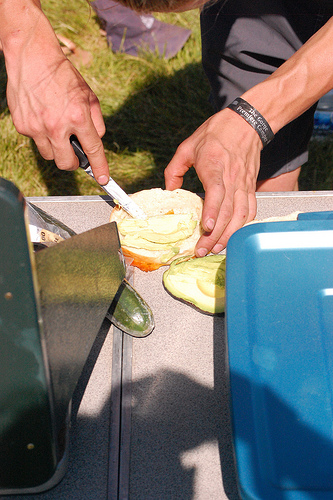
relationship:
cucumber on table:
[103, 280, 155, 338] [31, 189, 332, 498]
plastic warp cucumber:
[105, 280, 153, 337] [104, 277, 152, 337]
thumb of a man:
[163, 148, 188, 189] [0, 0, 333, 259]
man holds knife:
[6, 0, 329, 254] [67, 129, 136, 213]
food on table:
[110, 188, 206, 270] [31, 189, 332, 498]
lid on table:
[221, 216, 331, 408] [137, 277, 236, 446]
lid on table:
[0, 177, 94, 483] [23, 189, 297, 498]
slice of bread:
[117, 192, 201, 235] [117, 236, 196, 264]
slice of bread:
[118, 212, 194, 246] [121, 255, 170, 273]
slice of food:
[118, 212, 194, 246] [104, 188, 205, 274]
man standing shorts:
[6, 0, 329, 254] [196, 4, 324, 176]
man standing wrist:
[0, 0, 333, 259] [3, 13, 70, 71]